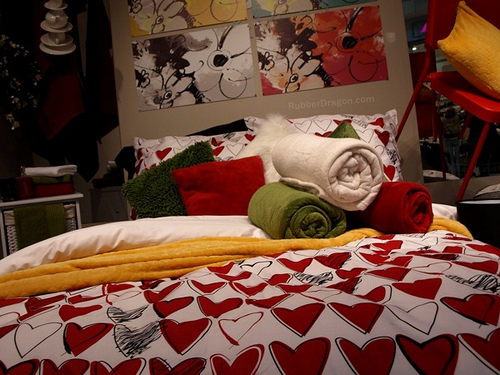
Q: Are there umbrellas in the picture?
A: No, there are no umbrellas.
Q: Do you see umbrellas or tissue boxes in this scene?
A: No, there are no umbrellas or tissue boxes.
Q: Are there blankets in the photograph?
A: Yes, there is a blanket.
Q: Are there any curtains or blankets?
A: Yes, there is a blanket.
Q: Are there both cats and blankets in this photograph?
A: No, there is a blanket but no cats.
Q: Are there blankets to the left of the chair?
A: Yes, there is a blanket to the left of the chair.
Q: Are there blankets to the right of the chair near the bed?
A: No, the blanket is to the left of the chair.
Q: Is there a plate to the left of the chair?
A: No, there is a blanket to the left of the chair.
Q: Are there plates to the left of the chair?
A: No, there is a blanket to the left of the chair.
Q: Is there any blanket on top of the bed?
A: Yes, there is a blanket on top of the bed.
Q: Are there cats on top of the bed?
A: No, there is a blanket on top of the bed.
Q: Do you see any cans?
A: No, there are no cans.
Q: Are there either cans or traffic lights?
A: No, there are no cans or traffic lights.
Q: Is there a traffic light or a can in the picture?
A: No, there are no cans or traffic lights.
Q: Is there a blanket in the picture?
A: Yes, there is a blanket.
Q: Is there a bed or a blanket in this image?
A: Yes, there is a blanket.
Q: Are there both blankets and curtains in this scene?
A: No, there is a blanket but no curtains.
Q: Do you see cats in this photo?
A: No, there are no cats.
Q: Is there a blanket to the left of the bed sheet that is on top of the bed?
A: Yes, there is a blanket to the left of the bed sheet.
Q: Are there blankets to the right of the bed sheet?
A: No, the blanket is to the left of the bed sheet.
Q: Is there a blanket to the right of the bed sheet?
A: No, the blanket is to the left of the bed sheet.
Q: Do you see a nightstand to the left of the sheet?
A: No, there is a blanket to the left of the sheet.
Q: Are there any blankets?
A: Yes, there is a blanket.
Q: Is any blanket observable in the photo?
A: Yes, there is a blanket.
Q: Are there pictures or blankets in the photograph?
A: Yes, there is a blanket.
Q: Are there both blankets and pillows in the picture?
A: Yes, there are both a blanket and a pillow.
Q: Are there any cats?
A: No, there are no cats.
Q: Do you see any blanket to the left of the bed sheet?
A: Yes, there is a blanket to the left of the bed sheet.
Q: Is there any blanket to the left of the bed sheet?
A: Yes, there is a blanket to the left of the bed sheet.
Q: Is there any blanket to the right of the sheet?
A: No, the blanket is to the left of the sheet.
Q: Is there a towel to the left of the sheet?
A: No, there is a blanket to the left of the sheet.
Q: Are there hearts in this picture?
A: Yes, there is a heart.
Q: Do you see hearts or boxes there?
A: Yes, there is a heart.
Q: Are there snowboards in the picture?
A: No, there are no snowboards.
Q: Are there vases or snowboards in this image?
A: No, there are no snowboards or vases.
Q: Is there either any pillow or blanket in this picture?
A: Yes, there is a blanket.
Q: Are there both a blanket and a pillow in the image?
A: Yes, there are both a blanket and a pillow.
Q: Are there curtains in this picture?
A: No, there are no curtains.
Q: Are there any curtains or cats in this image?
A: No, there are no curtains or cats.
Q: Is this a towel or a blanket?
A: This is a blanket.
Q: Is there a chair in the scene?
A: Yes, there is a chair.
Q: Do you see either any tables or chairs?
A: Yes, there is a chair.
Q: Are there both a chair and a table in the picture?
A: Yes, there are both a chair and a table.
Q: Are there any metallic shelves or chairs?
A: Yes, there is a metal chair.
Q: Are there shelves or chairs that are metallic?
A: Yes, the chair is metallic.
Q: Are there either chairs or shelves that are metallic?
A: Yes, the chair is metallic.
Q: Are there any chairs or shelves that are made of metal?
A: Yes, the chair is made of metal.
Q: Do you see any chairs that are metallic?
A: Yes, there is a metal chair.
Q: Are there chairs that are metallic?
A: Yes, there is a chair that is metallic.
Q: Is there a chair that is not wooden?
A: Yes, there is a metallic chair.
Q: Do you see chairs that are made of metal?
A: Yes, there is a chair that is made of metal.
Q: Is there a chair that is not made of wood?
A: Yes, there is a chair that is made of metal.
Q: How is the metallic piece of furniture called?
A: The piece of furniture is a chair.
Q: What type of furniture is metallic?
A: The furniture is a chair.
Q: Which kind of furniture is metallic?
A: The furniture is a chair.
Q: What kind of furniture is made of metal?
A: The furniture is a chair.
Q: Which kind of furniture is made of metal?
A: The furniture is a chair.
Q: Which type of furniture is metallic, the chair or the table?
A: The chair is metallic.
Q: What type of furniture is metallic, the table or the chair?
A: The chair is metallic.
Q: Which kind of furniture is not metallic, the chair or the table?
A: The table is not metallic.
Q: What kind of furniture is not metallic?
A: The furniture is a table.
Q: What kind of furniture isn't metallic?
A: The furniture is a table.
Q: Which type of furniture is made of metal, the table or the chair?
A: The chair is made of metal.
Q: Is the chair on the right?
A: Yes, the chair is on the right of the image.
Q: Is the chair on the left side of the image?
A: No, the chair is on the right of the image.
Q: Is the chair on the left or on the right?
A: The chair is on the right of the image.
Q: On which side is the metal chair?
A: The chair is on the right of the image.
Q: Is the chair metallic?
A: Yes, the chair is metallic.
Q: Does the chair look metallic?
A: Yes, the chair is metallic.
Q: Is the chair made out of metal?
A: Yes, the chair is made of metal.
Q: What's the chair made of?
A: The chair is made of metal.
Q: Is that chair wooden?
A: No, the chair is metallic.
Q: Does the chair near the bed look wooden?
A: No, the chair is metallic.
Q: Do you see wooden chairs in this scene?
A: No, there is a chair but it is metallic.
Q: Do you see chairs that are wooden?
A: No, there is a chair but it is metallic.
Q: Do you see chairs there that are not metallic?
A: No, there is a chair but it is metallic.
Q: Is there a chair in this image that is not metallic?
A: No, there is a chair but it is metallic.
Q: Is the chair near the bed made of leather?
A: No, the chair is made of metal.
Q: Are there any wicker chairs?
A: No, there is a chair but it is made of metal.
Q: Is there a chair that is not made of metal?
A: No, there is a chair but it is made of metal.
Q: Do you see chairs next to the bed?
A: Yes, there is a chair next to the bed.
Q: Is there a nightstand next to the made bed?
A: No, there is a chair next to the bed.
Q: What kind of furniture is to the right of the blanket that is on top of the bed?
A: The piece of furniture is a chair.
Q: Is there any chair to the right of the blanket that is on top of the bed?
A: Yes, there is a chair to the right of the blanket.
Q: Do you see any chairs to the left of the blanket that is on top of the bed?
A: No, the chair is to the right of the blanket.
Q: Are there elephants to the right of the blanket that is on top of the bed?
A: No, there is a chair to the right of the blanket.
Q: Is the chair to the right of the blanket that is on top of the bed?
A: Yes, the chair is to the right of the blanket.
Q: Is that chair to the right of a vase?
A: No, the chair is to the right of the blanket.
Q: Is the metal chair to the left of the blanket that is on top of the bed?
A: No, the chair is to the right of the blanket.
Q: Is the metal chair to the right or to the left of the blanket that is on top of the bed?
A: The chair is to the right of the blanket.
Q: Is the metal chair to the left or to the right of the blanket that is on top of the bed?
A: The chair is to the right of the blanket.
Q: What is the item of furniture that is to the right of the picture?
A: The piece of furniture is a chair.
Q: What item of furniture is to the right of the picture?
A: The piece of furniture is a chair.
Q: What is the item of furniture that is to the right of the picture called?
A: The piece of furniture is a chair.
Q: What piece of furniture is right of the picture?
A: The piece of furniture is a chair.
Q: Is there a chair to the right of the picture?
A: Yes, there is a chair to the right of the picture.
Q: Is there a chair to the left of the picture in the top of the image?
A: No, the chair is to the right of the picture.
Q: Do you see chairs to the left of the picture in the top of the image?
A: No, the chair is to the right of the picture.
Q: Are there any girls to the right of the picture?
A: No, there is a chair to the right of the picture.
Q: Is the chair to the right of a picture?
A: Yes, the chair is to the right of a picture.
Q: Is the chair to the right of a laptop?
A: No, the chair is to the right of a picture.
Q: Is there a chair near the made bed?
A: Yes, there is a chair near the bed.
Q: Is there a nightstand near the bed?
A: No, there is a chair near the bed.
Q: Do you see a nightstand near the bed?
A: No, there is a chair near the bed.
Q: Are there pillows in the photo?
A: Yes, there is a pillow.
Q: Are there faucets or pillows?
A: Yes, there is a pillow.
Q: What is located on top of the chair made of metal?
A: The pillow is on top of the chair.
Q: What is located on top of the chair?
A: The pillow is on top of the chair.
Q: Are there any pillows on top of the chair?
A: Yes, there is a pillow on top of the chair.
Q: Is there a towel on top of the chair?
A: No, there is a pillow on top of the chair.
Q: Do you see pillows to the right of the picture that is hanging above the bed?
A: Yes, there is a pillow to the right of the picture.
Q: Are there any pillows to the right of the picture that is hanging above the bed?
A: Yes, there is a pillow to the right of the picture.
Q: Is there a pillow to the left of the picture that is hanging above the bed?
A: No, the pillow is to the right of the picture.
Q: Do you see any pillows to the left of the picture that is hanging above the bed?
A: No, the pillow is to the right of the picture.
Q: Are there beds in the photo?
A: Yes, there is a bed.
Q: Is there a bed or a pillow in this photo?
A: Yes, there is a bed.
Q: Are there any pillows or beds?
A: Yes, there is a bed.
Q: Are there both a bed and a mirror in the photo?
A: No, there is a bed but no mirrors.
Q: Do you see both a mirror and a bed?
A: No, there is a bed but no mirrors.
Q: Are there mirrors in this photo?
A: No, there are no mirrors.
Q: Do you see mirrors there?
A: No, there are no mirrors.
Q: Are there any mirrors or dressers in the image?
A: No, there are no mirrors or dressers.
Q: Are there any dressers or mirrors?
A: No, there are no mirrors or dressers.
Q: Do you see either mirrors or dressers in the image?
A: No, there are no mirrors or dressers.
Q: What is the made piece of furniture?
A: The piece of furniture is a bed.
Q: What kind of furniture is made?
A: The furniture is a bed.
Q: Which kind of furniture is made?
A: The furniture is a bed.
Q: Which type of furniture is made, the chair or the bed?
A: The bed is made.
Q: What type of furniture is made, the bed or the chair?
A: The bed is made.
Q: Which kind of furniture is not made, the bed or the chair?
A: The chair is not made.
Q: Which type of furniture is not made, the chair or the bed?
A: The chair is not made.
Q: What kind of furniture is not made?
A: The furniture is a chair.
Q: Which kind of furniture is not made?
A: The furniture is a chair.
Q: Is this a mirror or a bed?
A: This is a bed.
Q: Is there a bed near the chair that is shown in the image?
A: Yes, there is a bed near the chair.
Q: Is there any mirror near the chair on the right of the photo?
A: No, there is a bed near the chair.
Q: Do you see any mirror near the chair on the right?
A: No, there is a bed near the chair.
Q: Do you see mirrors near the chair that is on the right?
A: No, there is a bed near the chair.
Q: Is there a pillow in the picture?
A: Yes, there is a pillow.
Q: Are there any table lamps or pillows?
A: Yes, there is a pillow.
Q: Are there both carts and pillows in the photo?
A: No, there is a pillow but no carts.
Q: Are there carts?
A: No, there are no carts.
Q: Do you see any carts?
A: No, there are no carts.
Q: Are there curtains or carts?
A: No, there are no carts or curtains.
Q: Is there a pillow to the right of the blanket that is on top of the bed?
A: No, the pillow is to the left of the blanket.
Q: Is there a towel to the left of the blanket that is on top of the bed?
A: No, there is a pillow to the left of the blanket.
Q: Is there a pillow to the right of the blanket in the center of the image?
A: No, the pillow is to the left of the blanket.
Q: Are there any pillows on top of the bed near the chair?
A: Yes, there is a pillow on top of the bed.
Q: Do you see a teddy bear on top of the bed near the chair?
A: No, there is a pillow on top of the bed.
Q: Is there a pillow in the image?
A: Yes, there is a pillow.